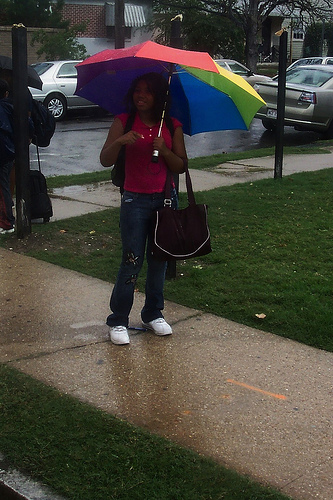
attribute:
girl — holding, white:
[101, 70, 185, 346]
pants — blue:
[108, 187, 180, 326]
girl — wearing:
[98, 70, 175, 342]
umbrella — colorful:
[72, 40, 267, 137]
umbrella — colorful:
[71, 39, 267, 162]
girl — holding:
[77, 66, 245, 285]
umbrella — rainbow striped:
[64, 35, 269, 142]